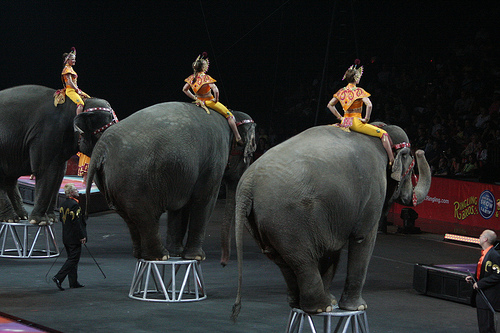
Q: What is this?
A: A circus.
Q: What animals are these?
A: Elephants.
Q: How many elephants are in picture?
A: Three.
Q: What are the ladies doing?
A: Riding the elephants.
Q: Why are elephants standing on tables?
A: Putting on a show.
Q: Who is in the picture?
A: Three ladies.